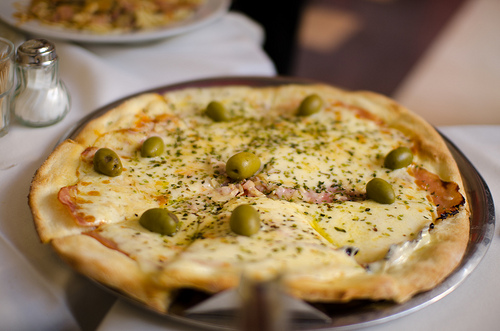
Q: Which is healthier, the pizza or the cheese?
A: The cheese is healthier than the pizza.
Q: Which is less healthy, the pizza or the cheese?
A: The pizza is less healthy than the cheese.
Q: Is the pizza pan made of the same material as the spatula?
A: Yes, both the pizza pan and the spatula are made of metal.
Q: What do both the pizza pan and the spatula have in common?
A: The material, both the pizza pan and the spatula are metallic.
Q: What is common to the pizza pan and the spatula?
A: The material, both the pizza pan and the spatula are metallic.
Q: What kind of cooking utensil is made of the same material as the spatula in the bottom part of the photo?
A: The pizza pan is made of the same material as the spatula.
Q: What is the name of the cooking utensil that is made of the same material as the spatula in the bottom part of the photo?
A: The cooking utensil is a pizza pan.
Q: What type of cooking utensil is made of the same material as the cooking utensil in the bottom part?
A: The pizza pan is made of the same material as the spatula.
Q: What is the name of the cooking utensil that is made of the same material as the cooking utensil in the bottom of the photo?
A: The cooking utensil is a pizza pan.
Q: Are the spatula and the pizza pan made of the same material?
A: Yes, both the spatula and the pizza pan are made of metal.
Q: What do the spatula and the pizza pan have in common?
A: The material, both the spatula and the pizza pan are metallic.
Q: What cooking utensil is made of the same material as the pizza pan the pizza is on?
A: The spatula is made of the same material as the pizza pan.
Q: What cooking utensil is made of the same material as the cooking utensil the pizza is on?
A: The spatula is made of the same material as the pizza pan.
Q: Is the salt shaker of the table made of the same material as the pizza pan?
A: No, the salt shaker is made of glass and the pizza pan is made of metal.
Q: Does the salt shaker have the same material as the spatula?
A: No, the salt shaker is made of glass and the spatula is made of metal.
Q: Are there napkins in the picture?
A: No, there are no napkins.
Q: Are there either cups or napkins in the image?
A: No, there are no napkins or cups.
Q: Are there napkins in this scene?
A: No, there are no napkins.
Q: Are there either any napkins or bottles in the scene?
A: No, there are no napkins or bottles.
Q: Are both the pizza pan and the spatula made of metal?
A: Yes, both the pizza pan and the spatula are made of metal.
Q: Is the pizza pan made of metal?
A: Yes, the pizza pan is made of metal.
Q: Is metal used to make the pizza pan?
A: Yes, the pizza pan is made of metal.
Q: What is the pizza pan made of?
A: The pizza pan is made of metal.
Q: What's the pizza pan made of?
A: The pizza pan is made of metal.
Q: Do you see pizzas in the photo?
A: Yes, there is a pizza.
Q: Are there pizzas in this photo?
A: Yes, there is a pizza.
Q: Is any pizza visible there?
A: Yes, there is a pizza.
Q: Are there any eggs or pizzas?
A: Yes, there is a pizza.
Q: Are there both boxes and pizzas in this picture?
A: No, there is a pizza but no boxes.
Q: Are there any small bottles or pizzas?
A: Yes, there is a small pizza.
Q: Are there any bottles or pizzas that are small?
A: Yes, the pizza is small.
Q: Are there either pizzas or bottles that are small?
A: Yes, the pizza is small.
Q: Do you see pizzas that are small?
A: Yes, there is a small pizza.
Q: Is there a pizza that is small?
A: Yes, there is a pizza that is small.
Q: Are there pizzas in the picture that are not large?
A: Yes, there is a small pizza.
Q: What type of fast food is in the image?
A: The fast food is a pizza.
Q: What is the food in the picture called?
A: The food is a pizza.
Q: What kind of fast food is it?
A: The food is a pizza.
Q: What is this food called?
A: This is a pizza.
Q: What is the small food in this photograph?
A: The food is a pizza.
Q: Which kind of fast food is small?
A: The fast food is a pizza.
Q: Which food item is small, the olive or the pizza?
A: The pizza is small.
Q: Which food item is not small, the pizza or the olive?
A: The olive is not small.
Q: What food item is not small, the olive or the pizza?
A: The olive is not small.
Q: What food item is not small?
A: The food item is an olive.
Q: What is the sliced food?
A: The food is a pizza.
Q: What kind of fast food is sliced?
A: The fast food is a pizza.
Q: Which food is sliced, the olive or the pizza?
A: The pizza is sliced.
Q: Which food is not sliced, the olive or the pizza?
A: The olive is not sliced.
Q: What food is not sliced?
A: The food is an olive.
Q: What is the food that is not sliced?
A: The food is an olive.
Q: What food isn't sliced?
A: The food is an olive.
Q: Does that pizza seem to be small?
A: Yes, the pizza is small.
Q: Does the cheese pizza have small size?
A: Yes, the pizza is small.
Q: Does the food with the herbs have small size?
A: Yes, the pizza is small.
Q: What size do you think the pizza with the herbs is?
A: The pizza is small.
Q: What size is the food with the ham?
A: The pizza is small.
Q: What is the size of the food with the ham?
A: The pizza is small.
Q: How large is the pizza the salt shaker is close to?
A: The pizza is small.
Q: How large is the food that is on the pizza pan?
A: The pizza is small.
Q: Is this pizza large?
A: No, the pizza is small.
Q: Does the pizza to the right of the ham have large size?
A: No, the pizza is small.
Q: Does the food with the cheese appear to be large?
A: No, the pizza is small.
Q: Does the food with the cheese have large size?
A: No, the pizza is small.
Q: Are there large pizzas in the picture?
A: No, there is a pizza but it is small.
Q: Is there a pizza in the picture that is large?
A: No, there is a pizza but it is small.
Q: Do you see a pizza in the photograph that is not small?
A: No, there is a pizza but it is small.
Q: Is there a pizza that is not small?
A: No, there is a pizza but it is small.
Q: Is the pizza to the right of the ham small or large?
A: The pizza is small.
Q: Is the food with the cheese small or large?
A: The pizza is small.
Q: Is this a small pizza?
A: Yes, this is a small pizza.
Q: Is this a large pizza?
A: No, this is a small pizza.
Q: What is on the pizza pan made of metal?
A: The pizza is on the pizza pan.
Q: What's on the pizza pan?
A: The pizza is on the pizza pan.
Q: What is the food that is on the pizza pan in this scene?
A: The food is a pizza.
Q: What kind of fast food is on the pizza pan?
A: The food is a pizza.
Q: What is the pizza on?
A: The pizza is on the pizza pan.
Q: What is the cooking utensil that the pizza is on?
A: The cooking utensil is a pizza pan.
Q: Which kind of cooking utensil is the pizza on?
A: The pizza is on the pizza pan.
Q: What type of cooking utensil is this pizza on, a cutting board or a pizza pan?
A: The pizza is on a pizza pan.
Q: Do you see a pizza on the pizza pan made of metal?
A: Yes, there is a pizza on the pizza pan.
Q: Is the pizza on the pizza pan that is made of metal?
A: Yes, the pizza is on the pizza pan.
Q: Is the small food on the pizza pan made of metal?
A: Yes, the pizza is on the pizza pan.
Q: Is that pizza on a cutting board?
A: No, the pizza is on the pizza pan.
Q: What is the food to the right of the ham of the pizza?
A: The food is a pizza.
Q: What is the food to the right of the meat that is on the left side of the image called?
A: The food is a pizza.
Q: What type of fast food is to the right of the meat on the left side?
A: The food is a pizza.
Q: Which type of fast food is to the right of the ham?
A: The food is a pizza.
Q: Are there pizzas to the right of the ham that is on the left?
A: Yes, there is a pizza to the right of the ham.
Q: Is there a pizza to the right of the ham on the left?
A: Yes, there is a pizza to the right of the ham.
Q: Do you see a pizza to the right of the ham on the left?
A: Yes, there is a pizza to the right of the ham.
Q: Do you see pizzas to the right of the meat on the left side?
A: Yes, there is a pizza to the right of the ham.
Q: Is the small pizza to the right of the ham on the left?
A: Yes, the pizza is to the right of the ham.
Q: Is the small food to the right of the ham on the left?
A: Yes, the pizza is to the right of the ham.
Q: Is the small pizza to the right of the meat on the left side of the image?
A: Yes, the pizza is to the right of the ham.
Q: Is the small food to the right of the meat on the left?
A: Yes, the pizza is to the right of the ham.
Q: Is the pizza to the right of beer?
A: No, the pizza is to the right of the ham.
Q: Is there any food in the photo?
A: Yes, there is food.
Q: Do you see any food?
A: Yes, there is food.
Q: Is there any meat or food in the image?
A: Yes, there is food.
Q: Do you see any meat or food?
A: Yes, there is food.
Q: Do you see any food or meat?
A: Yes, there is food.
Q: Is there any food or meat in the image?
A: Yes, there is food.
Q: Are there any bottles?
A: No, there are no bottles.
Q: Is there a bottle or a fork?
A: No, there are no bottles or forks.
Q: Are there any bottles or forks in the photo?
A: No, there are no bottles or forks.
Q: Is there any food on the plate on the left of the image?
A: Yes, there is food on the plate.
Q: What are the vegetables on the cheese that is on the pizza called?
A: The vegetables are herbs.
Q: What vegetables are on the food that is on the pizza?
A: The vegetables are herbs.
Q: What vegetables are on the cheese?
A: The vegetables are herbs.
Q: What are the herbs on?
A: The herbs are on the cheese.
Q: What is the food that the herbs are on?
A: The food is cheese.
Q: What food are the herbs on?
A: The herbs are on the cheese.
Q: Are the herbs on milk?
A: No, the herbs are on the cheese.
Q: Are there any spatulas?
A: Yes, there is a spatula.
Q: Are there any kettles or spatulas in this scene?
A: Yes, there is a spatula.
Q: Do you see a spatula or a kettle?
A: Yes, there is a spatula.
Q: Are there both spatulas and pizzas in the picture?
A: Yes, there are both a spatula and a pizza.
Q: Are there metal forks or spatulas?
A: Yes, there is a metal spatula.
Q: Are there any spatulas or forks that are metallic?
A: Yes, the spatula is metallic.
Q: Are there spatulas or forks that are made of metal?
A: Yes, the spatula is made of metal.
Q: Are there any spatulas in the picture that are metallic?
A: Yes, there is a spatula that is metallic.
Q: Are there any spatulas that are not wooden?
A: Yes, there is a metallic spatula.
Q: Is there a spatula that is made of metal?
A: Yes, there is a spatula that is made of metal.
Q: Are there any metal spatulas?
A: Yes, there is a spatula that is made of metal.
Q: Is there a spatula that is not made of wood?
A: Yes, there is a spatula that is made of metal.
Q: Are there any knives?
A: No, there are no knives.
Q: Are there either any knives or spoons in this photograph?
A: No, there are no knives or spoons.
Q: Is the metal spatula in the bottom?
A: Yes, the spatula is in the bottom of the image.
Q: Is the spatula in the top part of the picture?
A: No, the spatula is in the bottom of the image.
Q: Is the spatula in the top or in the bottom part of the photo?
A: The spatula is in the bottom of the image.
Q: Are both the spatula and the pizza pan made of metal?
A: Yes, both the spatula and the pizza pan are made of metal.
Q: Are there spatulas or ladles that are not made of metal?
A: No, there is a spatula but it is made of metal.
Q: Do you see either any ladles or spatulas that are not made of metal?
A: No, there is a spatula but it is made of metal.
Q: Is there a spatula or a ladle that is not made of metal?
A: No, there is a spatula but it is made of metal.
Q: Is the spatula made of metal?
A: Yes, the spatula is made of metal.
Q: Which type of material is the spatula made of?
A: The spatula is made of metal.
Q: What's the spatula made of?
A: The spatula is made of metal.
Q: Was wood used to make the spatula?
A: No, the spatula is made of metal.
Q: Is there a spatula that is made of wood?
A: No, there is a spatula but it is made of metal.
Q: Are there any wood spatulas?
A: No, there is a spatula but it is made of metal.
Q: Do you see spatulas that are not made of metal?
A: No, there is a spatula but it is made of metal.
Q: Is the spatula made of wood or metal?
A: The spatula is made of metal.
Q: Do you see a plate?
A: Yes, there is a plate.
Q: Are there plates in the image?
A: Yes, there is a plate.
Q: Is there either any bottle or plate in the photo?
A: Yes, there is a plate.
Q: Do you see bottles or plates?
A: Yes, there is a plate.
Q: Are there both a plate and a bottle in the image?
A: No, there is a plate but no bottles.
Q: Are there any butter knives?
A: No, there are no butter knives.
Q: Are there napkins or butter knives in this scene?
A: No, there are no butter knives or napkins.